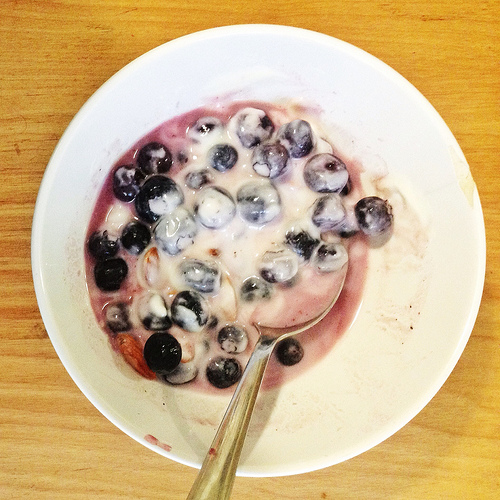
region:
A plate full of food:
[8, 33, 489, 470]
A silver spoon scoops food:
[161, 227, 361, 487]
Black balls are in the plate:
[85, 101, 410, 406]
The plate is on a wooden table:
[5, 33, 483, 488]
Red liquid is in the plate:
[79, 90, 396, 423]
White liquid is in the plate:
[125, 98, 385, 391]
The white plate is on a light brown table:
[8, 33, 485, 476]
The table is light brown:
[12, 121, 494, 495]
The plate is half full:
[76, 88, 412, 414]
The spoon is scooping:
[158, 211, 378, 488]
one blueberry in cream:
[237, 105, 272, 141]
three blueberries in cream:
[237, 102, 308, 177]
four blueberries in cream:
[195, 105, 285, 176]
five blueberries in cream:
[100, 295, 200, 385]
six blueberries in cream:
[230, 105, 345, 225]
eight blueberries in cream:
[186, 100, 306, 221]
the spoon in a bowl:
[185, 235, 350, 495]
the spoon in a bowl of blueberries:
[170, 216, 347, 496]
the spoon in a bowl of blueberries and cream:
[184, 231, 346, 498]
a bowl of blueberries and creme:
[29, 27, 483, 477]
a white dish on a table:
[0, 0, 498, 492]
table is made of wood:
[4, 11, 496, 498]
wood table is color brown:
[8, 6, 493, 497]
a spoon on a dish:
[166, 228, 356, 491]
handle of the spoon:
[195, 332, 285, 492]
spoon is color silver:
[165, 235, 355, 496]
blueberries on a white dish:
[83, 97, 404, 392]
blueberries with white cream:
[80, 90, 395, 400]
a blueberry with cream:
[291, 140, 346, 190]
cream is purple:
[77, 98, 195, 259]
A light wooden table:
[5, 6, 498, 493]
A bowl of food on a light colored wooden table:
[0, 1, 495, 498]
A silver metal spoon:
[179, 235, 349, 499]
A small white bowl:
[34, 21, 484, 476]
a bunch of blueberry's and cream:
[83, 107, 392, 391]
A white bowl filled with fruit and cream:
[32, 25, 483, 473]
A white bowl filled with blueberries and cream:
[31, 23, 486, 476]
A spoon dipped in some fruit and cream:
[183, 242, 347, 499]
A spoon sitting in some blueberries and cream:
[182, 242, 348, 499]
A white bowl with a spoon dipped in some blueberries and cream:
[34, 22, 486, 499]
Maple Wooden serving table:
[17, 403, 74, 456]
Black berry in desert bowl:
[144, 332, 186, 377]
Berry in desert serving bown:
[109, 165, 146, 203]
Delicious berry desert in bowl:
[28, 19, 498, 475]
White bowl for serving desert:
[295, 399, 342, 446]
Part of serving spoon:
[231, 376, 249, 459]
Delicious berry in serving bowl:
[357, 195, 393, 239]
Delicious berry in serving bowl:
[233, 106, 275, 148]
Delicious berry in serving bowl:
[134, 142, 175, 175]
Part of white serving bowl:
[53, 309, 87, 346]